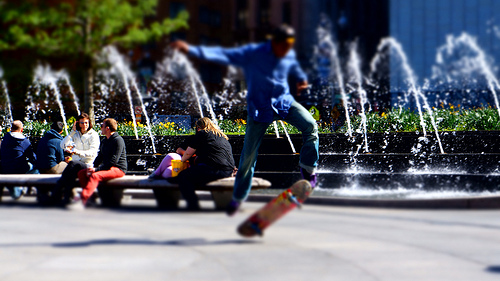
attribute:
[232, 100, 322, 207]
pants — faded blue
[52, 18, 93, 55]
leaves — green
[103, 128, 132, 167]
top — black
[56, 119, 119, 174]
jacket — white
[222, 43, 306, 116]
shirt — blue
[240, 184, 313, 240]
skateboard — red 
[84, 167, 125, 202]
pants — orange 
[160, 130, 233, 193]
outfit — black 